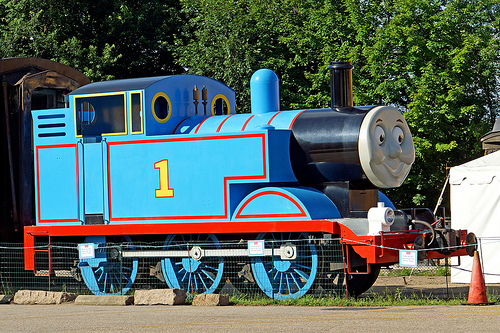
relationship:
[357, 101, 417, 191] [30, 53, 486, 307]
face on train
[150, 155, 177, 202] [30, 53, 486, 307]
number on train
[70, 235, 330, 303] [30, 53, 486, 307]
wheels on train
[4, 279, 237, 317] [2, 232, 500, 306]
rocks along fence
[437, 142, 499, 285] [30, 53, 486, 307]
building behind train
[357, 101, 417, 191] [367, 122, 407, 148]
face has eyes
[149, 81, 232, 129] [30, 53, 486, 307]
windows on train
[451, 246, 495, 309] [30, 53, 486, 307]
cone in front of train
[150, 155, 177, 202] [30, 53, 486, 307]
number on side of train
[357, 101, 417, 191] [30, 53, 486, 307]
face on front of train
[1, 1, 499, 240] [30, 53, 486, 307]
trees behind train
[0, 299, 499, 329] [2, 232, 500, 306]
road near fence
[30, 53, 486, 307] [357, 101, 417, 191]
train has face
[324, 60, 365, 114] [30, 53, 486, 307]
pipe on train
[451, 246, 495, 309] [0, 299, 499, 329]
cone on road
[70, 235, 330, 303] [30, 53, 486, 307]
wheels under train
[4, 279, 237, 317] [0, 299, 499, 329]
rocks near road